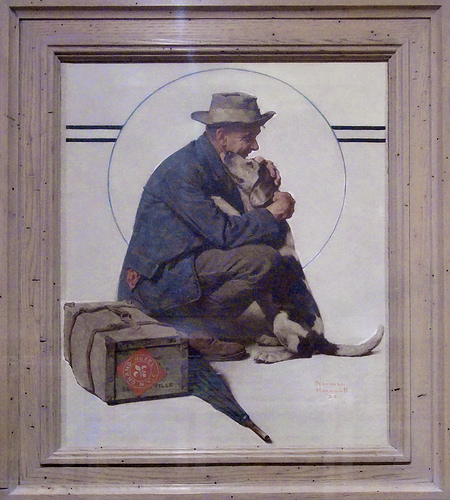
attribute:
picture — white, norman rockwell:
[58, 60, 390, 451]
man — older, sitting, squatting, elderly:
[114, 91, 291, 358]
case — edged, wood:
[59, 298, 192, 407]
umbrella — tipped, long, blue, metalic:
[187, 338, 271, 447]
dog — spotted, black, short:
[207, 148, 384, 370]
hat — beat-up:
[186, 92, 276, 131]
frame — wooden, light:
[1, 1, 448, 499]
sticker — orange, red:
[117, 346, 167, 401]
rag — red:
[123, 267, 143, 294]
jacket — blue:
[108, 133, 280, 318]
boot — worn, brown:
[178, 317, 247, 364]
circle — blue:
[104, 67, 346, 269]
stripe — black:
[65, 119, 125, 132]